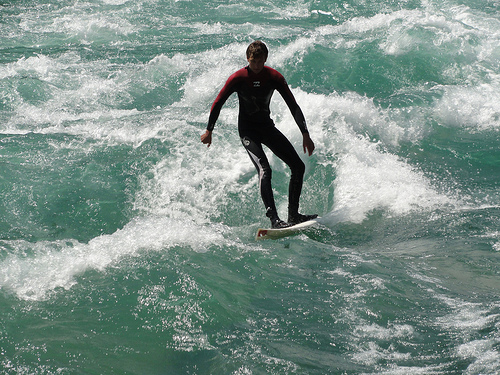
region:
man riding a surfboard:
[199, 30, 344, 247]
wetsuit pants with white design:
[235, 127, 305, 207]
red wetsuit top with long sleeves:
[202, 60, 303, 136]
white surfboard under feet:
[253, 210, 324, 245]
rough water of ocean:
[322, 155, 425, 295]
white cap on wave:
[72, 209, 190, 274]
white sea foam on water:
[330, 293, 441, 350]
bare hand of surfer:
[196, 124, 217, 151]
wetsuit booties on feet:
[266, 211, 318, 233]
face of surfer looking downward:
[242, 45, 273, 77]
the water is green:
[69, 247, 215, 374]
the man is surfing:
[186, 40, 339, 245]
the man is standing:
[197, 30, 343, 254]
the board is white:
[245, 200, 332, 238]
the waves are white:
[23, 157, 193, 311]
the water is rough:
[21, 142, 199, 321]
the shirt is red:
[196, 43, 308, 140]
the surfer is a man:
[200, 38, 351, 256]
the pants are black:
[225, 126, 321, 237]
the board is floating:
[227, 197, 337, 249]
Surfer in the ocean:
[191, 26, 343, 250]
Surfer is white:
[246, 211, 333, 246]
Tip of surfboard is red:
[246, 216, 282, 251]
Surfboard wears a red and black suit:
[174, 30, 356, 262]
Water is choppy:
[0, 0, 498, 370]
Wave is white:
[317, 102, 404, 212]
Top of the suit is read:
[191, 34, 343, 240]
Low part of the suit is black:
[184, 22, 336, 253]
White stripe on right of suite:
[236, 134, 278, 216]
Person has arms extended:
[171, 29, 343, 262]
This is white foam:
[41, 231, 126, 266]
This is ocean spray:
[317, 98, 406, 170]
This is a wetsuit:
[198, 67, 351, 247]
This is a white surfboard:
[238, 212, 339, 247]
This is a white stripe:
[246, 139, 277, 238]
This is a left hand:
[293, 125, 339, 159]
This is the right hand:
[187, 119, 232, 169]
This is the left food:
[281, 205, 338, 228]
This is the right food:
[258, 208, 291, 233]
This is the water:
[240, 284, 318, 336]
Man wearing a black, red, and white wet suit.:
[196, 40, 322, 240]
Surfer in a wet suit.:
[197, 37, 319, 238]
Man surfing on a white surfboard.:
[201, 39, 324, 241]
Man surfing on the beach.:
[10, 5, 489, 365]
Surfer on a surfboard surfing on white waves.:
[25, 16, 478, 310]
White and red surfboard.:
[244, 212, 338, 239]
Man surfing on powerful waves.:
[16, 16, 485, 268]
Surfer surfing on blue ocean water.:
[1, 1, 498, 373]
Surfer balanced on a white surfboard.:
[200, 40, 332, 241]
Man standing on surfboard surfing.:
[145, 15, 417, 286]